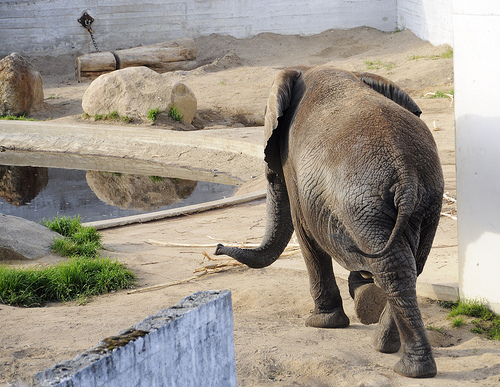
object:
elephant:
[212, 70, 461, 376]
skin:
[310, 90, 434, 272]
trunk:
[211, 166, 296, 289]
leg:
[366, 236, 456, 381]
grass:
[4, 267, 161, 310]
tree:
[59, 50, 218, 84]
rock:
[76, 64, 192, 152]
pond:
[41, 161, 149, 243]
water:
[11, 141, 227, 234]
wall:
[120, 9, 333, 28]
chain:
[83, 12, 105, 41]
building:
[12, 13, 498, 154]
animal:
[229, 44, 462, 386]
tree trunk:
[62, 30, 207, 71]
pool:
[4, 104, 290, 248]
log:
[63, 42, 211, 72]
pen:
[4, 1, 449, 377]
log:
[72, 39, 209, 74]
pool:
[4, 110, 286, 240]